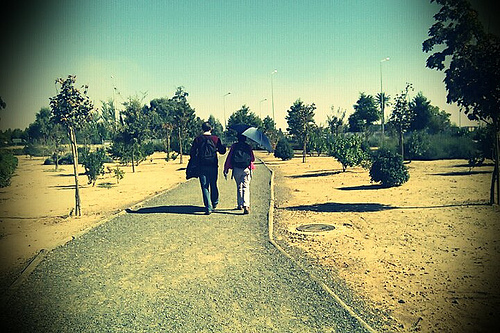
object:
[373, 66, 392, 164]
pole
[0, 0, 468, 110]
sky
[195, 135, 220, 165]
backpack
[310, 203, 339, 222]
sand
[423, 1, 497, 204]
tree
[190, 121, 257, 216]
couple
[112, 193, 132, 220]
gravel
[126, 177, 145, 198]
dirt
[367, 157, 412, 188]
shrub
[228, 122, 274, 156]
umbrella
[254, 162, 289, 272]
edge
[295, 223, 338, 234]
hole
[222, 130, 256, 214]
person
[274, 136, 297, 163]
bush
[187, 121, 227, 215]
man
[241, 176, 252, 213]
leg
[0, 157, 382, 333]
path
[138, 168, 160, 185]
soil